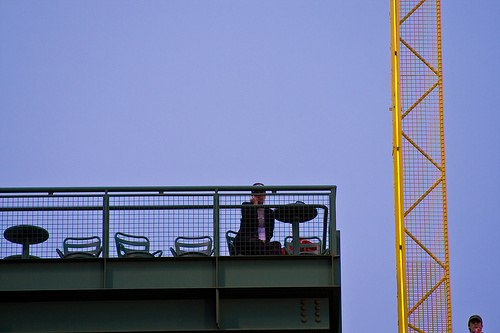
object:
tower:
[388, 1, 451, 332]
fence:
[0, 185, 337, 260]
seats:
[112, 232, 163, 260]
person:
[233, 182, 282, 254]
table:
[3, 222, 49, 259]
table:
[272, 202, 320, 254]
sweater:
[232, 202, 275, 254]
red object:
[282, 239, 318, 255]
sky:
[0, 0, 499, 332]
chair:
[168, 235, 217, 256]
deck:
[0, 185, 343, 332]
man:
[468, 314, 483, 332]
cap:
[468, 313, 485, 323]